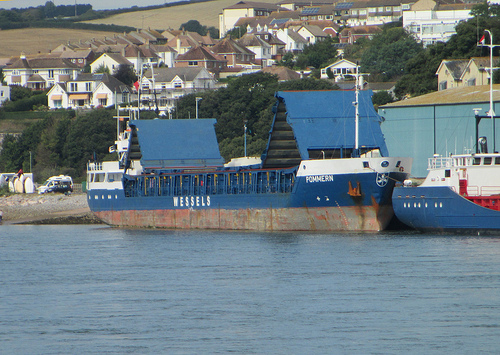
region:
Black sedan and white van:
[34, 173, 76, 196]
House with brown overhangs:
[47, 73, 121, 112]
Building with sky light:
[232, 1, 414, 29]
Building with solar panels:
[227, 0, 406, 27]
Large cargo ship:
[77, 72, 415, 236]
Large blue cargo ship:
[86, 88, 406, 245]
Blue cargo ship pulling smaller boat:
[80, 84, 498, 234]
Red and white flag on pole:
[474, 25, 494, 117]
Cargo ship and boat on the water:
[82, 79, 499, 295]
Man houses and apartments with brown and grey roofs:
[4, 21, 217, 103]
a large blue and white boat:
[78, 154, 410, 235]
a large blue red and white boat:
[390, 145, 495, 230]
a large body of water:
[0, 222, 496, 352]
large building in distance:
[2, 56, 72, 89]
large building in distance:
[42, 72, 122, 107]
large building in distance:
[137, 60, 209, 110]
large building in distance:
[400, 3, 471, 45]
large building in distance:
[216, 0, 294, 38]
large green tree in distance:
[365, 26, 425, 77]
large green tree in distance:
[66, 109, 110, 164]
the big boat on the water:
[87, 89, 413, 232]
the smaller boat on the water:
[392, 153, 499, 234]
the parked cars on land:
[38, 174, 73, 196]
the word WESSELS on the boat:
[172, 195, 211, 207]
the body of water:
[0, 222, 497, 353]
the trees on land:
[0, 0, 498, 182]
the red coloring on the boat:
[431, 168, 498, 212]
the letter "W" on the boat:
[172, 194, 179, 206]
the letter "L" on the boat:
[200, 196, 205, 206]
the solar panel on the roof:
[298, 5, 318, 15]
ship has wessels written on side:
[63, 109, 398, 259]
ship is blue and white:
[73, 106, 410, 260]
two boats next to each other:
[80, 120, 497, 265]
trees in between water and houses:
[17, 22, 365, 246]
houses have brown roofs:
[11, 10, 306, 141]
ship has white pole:
[295, 56, 385, 254]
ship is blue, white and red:
[390, 107, 491, 262]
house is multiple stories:
[41, 52, 141, 122]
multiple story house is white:
[31, 55, 131, 120]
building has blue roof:
[233, 50, 388, 156]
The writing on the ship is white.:
[173, 197, 213, 206]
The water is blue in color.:
[171, 286, 283, 334]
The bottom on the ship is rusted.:
[113, 208, 208, 225]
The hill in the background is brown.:
[11, 31, 53, 48]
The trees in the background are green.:
[23, 2, 54, 19]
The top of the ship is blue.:
[148, 122, 215, 153]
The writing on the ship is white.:
[308, 176, 334, 181]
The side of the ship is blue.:
[298, 188, 340, 202]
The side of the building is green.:
[398, 114, 430, 149]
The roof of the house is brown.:
[161, 68, 170, 76]